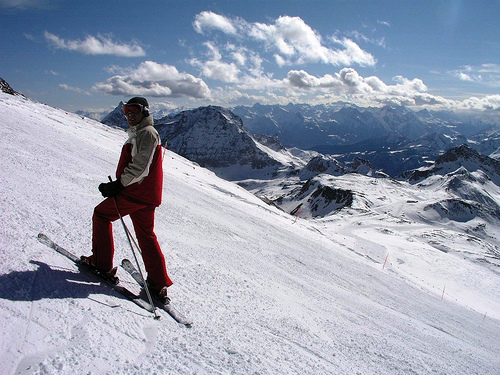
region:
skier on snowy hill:
[34, 92, 194, 330]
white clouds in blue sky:
[22, 16, 83, 64]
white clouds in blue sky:
[364, 51, 409, 83]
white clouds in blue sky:
[390, 109, 441, 137]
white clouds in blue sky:
[272, 29, 316, 67]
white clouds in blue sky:
[237, 39, 281, 76]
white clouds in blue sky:
[142, 5, 194, 56]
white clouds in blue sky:
[210, 48, 268, 93]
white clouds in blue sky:
[75, 9, 162, 64]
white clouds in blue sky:
[260, 39, 347, 97]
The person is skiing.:
[33, 95, 218, 343]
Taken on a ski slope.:
[2, 2, 499, 372]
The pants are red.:
[81, 191, 179, 313]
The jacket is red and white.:
[102, 127, 177, 218]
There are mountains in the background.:
[154, 83, 499, 153]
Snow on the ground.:
[238, 248, 353, 330]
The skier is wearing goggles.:
[115, 101, 151, 118]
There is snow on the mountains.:
[173, 107, 260, 168]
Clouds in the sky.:
[196, 19, 386, 98]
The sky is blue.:
[8, 4, 133, 91]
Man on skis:
[35, 229, 193, 331]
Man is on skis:
[34, 225, 196, 330]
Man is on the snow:
[35, 225, 196, 330]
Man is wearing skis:
[33, 226, 191, 331]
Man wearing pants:
[85, 185, 172, 293]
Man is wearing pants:
[90, 183, 171, 289]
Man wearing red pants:
[90, 190, 176, 287]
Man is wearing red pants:
[90, 192, 173, 289]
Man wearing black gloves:
[95, 172, 122, 197]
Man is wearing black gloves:
[95, 177, 126, 199]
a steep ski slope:
[0, 89, 499, 374]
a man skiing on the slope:
[79, 96, 172, 303]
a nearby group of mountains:
[99, 100, 499, 318]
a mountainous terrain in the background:
[149, 100, 499, 178]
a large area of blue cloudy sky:
[0, 0, 499, 122]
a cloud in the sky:
[42, 17, 144, 57]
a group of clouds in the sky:
[192, 10, 391, 68]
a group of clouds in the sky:
[90, 60, 210, 99]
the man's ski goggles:
[121, 103, 149, 116]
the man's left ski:
[36, 232, 156, 313]